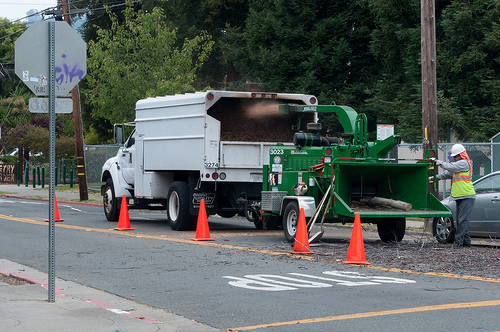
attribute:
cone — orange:
[325, 204, 379, 272]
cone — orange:
[341, 208, 368, 270]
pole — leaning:
[69, 84, 91, 203]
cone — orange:
[180, 190, 228, 242]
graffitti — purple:
[40, 52, 95, 92]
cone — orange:
[343, 210, 370, 262]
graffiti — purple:
[51, 50, 82, 88]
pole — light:
[409, 72, 431, 104]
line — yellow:
[229, 289, 309, 330]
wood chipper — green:
[259, 104, 449, 253]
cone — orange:
[341, 209, 373, 271]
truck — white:
[125, 92, 239, 200]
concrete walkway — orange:
[29, 278, 122, 329]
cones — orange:
[49, 188, 373, 279]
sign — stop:
[14, 21, 86, 95]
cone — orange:
[179, 197, 219, 249]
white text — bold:
[217, 252, 410, 309]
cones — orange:
[189, 194, 376, 269]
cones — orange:
[295, 198, 372, 276]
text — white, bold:
[224, 258, 444, 304]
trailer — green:
[258, 101, 462, 243]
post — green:
[40, 164, 47, 194]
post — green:
[23, 160, 30, 186]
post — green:
[29, 165, 38, 190]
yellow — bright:
[447, 166, 477, 199]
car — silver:
[430, 175, 484, 246]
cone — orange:
[343, 212, 366, 266]